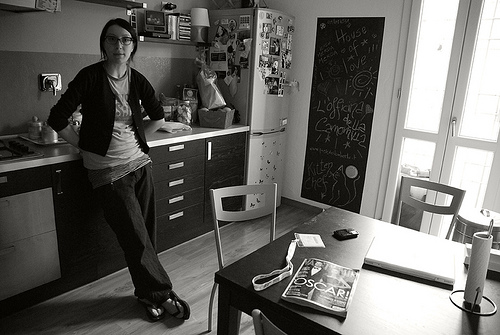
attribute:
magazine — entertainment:
[276, 250, 362, 325]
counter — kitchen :
[121, 80, 241, 152]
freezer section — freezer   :
[237, 135, 288, 215]